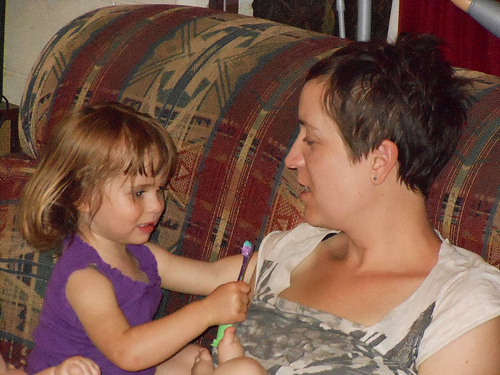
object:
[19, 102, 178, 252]
hair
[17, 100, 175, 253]
head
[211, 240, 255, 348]
tooth brush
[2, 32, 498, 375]
people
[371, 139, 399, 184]
ear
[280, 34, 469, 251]
green grass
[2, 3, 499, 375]
couch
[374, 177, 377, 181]
earring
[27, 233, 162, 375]
purple shirt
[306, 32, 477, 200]
hair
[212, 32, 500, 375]
woman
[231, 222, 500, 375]
shirt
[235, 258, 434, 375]
pictures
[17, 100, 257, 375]
child